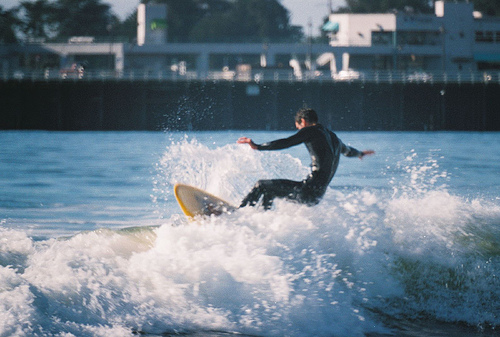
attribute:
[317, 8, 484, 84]
building — white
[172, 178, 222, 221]
board — white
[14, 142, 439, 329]
water — white, blue, big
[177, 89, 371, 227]
man — surfing, white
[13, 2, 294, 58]
trees — green